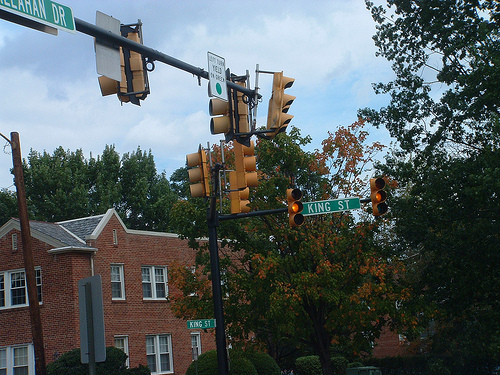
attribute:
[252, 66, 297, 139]
traffic light — hanging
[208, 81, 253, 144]
traffic light — hanging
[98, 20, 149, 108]
traffic light — hanging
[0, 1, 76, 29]
street sign — green, white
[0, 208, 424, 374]
building — brick, two-story, red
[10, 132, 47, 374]
electrical pole — wooden, brown, large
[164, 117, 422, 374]
tree — red, is, colorful, changing color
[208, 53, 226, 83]
writing — left turn yield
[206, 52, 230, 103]
sign — yield sign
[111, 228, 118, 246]
window — small, vent window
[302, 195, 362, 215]
sign — for king st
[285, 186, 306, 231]
traffic light — yellow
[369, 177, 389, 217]
traffic light — yellow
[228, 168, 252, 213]
traffic light — hanging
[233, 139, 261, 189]
traffic light — hanging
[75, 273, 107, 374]
sign — large, white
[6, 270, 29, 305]
window — large, white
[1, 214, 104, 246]
roof — gray, slanted, trianglular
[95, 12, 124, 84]
sign — gray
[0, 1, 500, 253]
sky — blue, cloudy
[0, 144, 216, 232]
trees — green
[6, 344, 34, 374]
frame — white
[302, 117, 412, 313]
leaves — brown